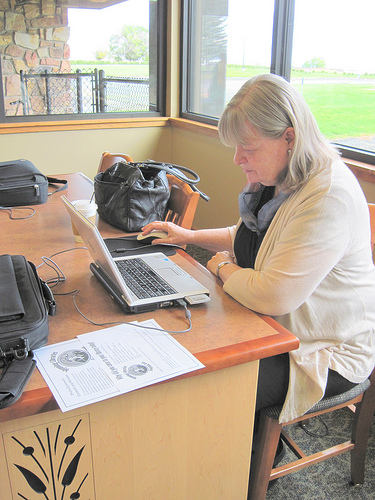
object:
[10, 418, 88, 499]
stencil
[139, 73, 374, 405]
woman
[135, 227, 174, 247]
mouse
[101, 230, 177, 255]
mousepad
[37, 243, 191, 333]
cords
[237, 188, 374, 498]
chair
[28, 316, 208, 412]
papers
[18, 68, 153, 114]
black fencing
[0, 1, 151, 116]
window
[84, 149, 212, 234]
handbag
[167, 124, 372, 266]
wall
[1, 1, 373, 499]
building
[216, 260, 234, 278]
watch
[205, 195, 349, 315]
arm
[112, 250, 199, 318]
keyboard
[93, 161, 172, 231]
purse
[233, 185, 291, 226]
woman's scarf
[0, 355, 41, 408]
strap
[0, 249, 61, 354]
bag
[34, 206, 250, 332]
laptop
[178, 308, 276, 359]
table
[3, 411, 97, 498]
pattern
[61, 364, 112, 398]
writing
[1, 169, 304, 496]
desk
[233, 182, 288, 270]
scarf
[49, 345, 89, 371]
writing